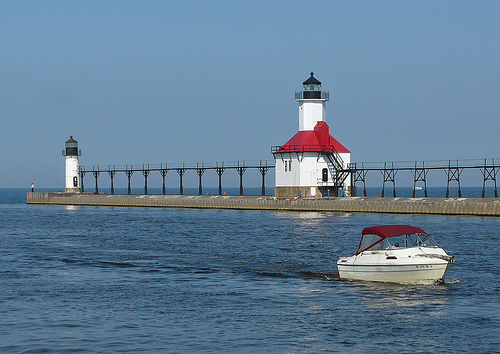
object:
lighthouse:
[59, 133, 84, 195]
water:
[0, 184, 499, 353]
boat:
[336, 222, 455, 286]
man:
[27, 181, 38, 194]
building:
[272, 69, 354, 199]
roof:
[274, 120, 350, 164]